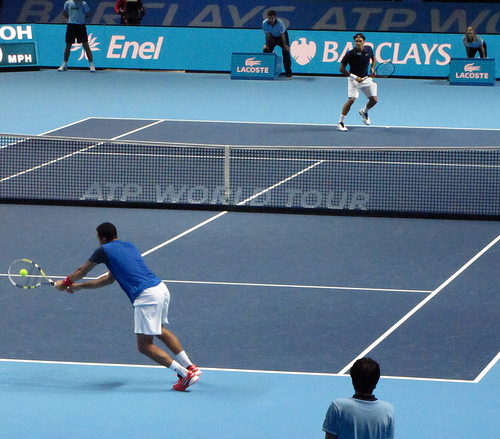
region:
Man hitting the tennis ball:
[7, 220, 204, 390]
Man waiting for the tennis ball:
[331, 31, 396, 131]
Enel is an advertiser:
[106, 33, 163, 65]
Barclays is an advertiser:
[323, 40, 452, 69]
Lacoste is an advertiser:
[450, 58, 490, 82]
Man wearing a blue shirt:
[85, 240, 162, 302]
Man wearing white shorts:
[132, 284, 173, 336]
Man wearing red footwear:
[173, 363, 203, 392]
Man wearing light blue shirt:
[320, 392, 401, 437]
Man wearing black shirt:
[341, 44, 376, 73]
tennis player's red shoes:
[173, 362, 198, 392]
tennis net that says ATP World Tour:
[73, 151, 369, 211]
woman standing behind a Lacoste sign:
[449, 28, 494, 83]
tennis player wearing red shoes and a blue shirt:
[7, 220, 201, 393]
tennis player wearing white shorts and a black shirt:
[337, 33, 388, 134]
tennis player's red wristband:
[58, 275, 78, 291]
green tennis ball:
[16, 265, 31, 280]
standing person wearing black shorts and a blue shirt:
[57, 0, 94, 73]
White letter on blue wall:
[103, 28, 120, 68]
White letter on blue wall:
[118, 39, 140, 68]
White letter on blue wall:
[136, 37, 151, 62]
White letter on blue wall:
[150, 32, 165, 69]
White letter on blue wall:
[313, 36, 341, 72]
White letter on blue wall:
[433, 39, 447, 75]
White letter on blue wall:
[418, 37, 434, 80]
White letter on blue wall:
[400, 37, 421, 79]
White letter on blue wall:
[390, 34, 407, 76]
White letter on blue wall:
[373, 36, 392, 76]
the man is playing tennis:
[2, 163, 252, 413]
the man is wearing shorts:
[106, 257, 177, 352]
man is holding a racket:
[2, 244, 124, 316]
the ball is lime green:
[2, 250, 42, 300]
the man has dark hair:
[91, 218, 121, 250]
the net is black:
[173, 117, 441, 239]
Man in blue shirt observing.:
[257, 7, 296, 89]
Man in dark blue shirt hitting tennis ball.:
[5, 219, 201, 394]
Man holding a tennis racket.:
[336, 31, 399, 133]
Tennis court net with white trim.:
[1, 129, 496, 219]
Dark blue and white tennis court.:
[0, 114, 498, 384]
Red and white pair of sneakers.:
[172, 363, 202, 393]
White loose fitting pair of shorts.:
[132, 278, 171, 340]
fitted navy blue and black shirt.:
[88, 237, 163, 304]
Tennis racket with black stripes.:
[7, 257, 59, 290]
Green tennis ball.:
[19, 267, 26, 277]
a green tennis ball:
[20, 263, 29, 275]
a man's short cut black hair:
[348, 357, 382, 399]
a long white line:
[332, 234, 498, 377]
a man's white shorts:
[129, 280, 171, 338]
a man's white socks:
[175, 345, 192, 365]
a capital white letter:
[102, 33, 127, 63]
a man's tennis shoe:
[337, 120, 347, 128]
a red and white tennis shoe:
[172, 368, 198, 391]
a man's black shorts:
[62, 20, 86, 44]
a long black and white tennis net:
[0, 125, 498, 233]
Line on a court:
[377, 310, 410, 344]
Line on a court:
[262, 363, 313, 377]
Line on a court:
[406, 360, 460, 394]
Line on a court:
[218, 358, 312, 383]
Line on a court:
[263, 269, 335, 299]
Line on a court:
[34, 349, 99, 379]